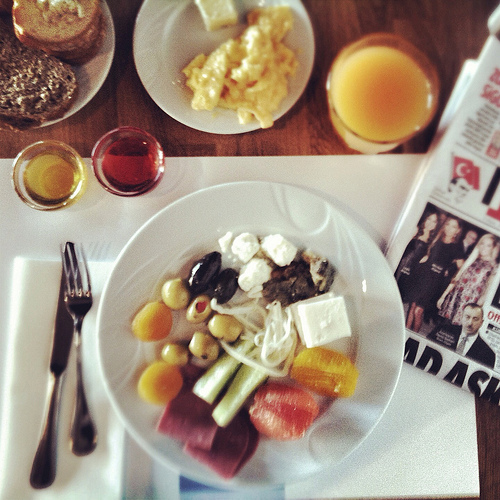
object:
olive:
[162, 275, 191, 310]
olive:
[186, 294, 212, 324]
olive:
[208, 313, 244, 342]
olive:
[189, 330, 219, 360]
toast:
[0, 0, 105, 122]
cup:
[90, 125, 167, 198]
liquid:
[101, 137, 157, 189]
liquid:
[22, 153, 78, 202]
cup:
[10, 140, 87, 212]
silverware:
[27, 241, 93, 491]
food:
[131, 232, 353, 475]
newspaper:
[386, 4, 499, 405]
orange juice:
[324, 32, 441, 154]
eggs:
[179, 0, 302, 130]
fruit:
[129, 250, 359, 482]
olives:
[160, 276, 245, 367]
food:
[223, 268, 342, 355]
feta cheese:
[210, 231, 353, 377]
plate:
[132, 0, 317, 137]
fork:
[59, 243, 97, 457]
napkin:
[1, 257, 121, 499]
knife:
[29, 243, 79, 491]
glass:
[324, 31, 440, 154]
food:
[181, 0, 301, 129]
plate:
[96, 180, 407, 496]